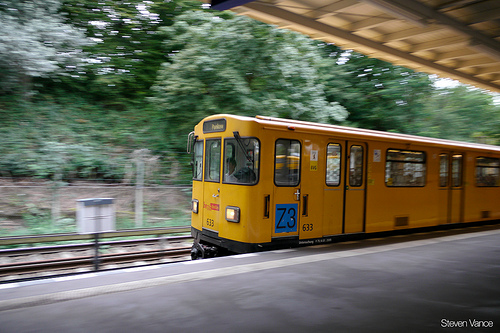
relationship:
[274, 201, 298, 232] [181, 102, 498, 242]
notation on top of train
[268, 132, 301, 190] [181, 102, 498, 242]
window on side of train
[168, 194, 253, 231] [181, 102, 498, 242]
front lights of train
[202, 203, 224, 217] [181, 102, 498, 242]
red on front of train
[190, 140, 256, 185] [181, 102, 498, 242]
windows on front of train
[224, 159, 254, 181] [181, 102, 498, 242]
driver in front of train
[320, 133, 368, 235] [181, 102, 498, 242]
doors attached to train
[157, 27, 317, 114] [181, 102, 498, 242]
trees on side of train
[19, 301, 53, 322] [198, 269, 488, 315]
part of floor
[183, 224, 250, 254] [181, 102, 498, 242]
edge of train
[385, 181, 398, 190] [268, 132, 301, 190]
part of window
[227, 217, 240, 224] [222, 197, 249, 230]
part of headlight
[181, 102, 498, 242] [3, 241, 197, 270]
train on top of track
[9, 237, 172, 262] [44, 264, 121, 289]
tracks on top of ground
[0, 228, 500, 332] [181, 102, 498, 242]
floor next to train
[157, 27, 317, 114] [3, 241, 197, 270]
trees next to track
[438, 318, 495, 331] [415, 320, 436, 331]
writing in corner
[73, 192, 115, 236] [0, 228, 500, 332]
sign next to floor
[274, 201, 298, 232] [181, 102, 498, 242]
notation attached to train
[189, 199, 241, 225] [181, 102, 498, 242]
front lights attached to train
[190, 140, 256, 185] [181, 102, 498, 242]
front windows attached to train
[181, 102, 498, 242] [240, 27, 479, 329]
train inside of station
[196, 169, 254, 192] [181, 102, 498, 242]
windshield attached to train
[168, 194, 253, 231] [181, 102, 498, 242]
front lights attached to train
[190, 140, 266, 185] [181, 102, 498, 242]
windows attached to train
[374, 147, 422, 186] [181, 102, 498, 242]
side window attached to train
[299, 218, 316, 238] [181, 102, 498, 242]
number attached to train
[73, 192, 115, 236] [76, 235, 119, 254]
box attached to post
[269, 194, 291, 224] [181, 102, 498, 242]
notation attached to train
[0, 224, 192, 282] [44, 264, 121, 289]
tracks on top of ground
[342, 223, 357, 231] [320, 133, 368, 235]
part of doors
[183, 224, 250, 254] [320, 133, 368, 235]
edge of doors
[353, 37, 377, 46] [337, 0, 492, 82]
part of shade